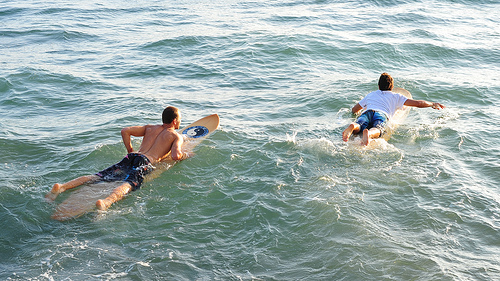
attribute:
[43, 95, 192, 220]
man — muscular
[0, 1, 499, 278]
water — greenish blue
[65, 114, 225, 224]
surfboard — white, blue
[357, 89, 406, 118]
t-shirt — white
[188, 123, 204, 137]
logo — yin yang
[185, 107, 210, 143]
logo — black, white, blue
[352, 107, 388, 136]
trunks — blue 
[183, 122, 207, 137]
logo — blue, white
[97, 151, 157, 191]
swim trunks — black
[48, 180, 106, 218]
feet — bare